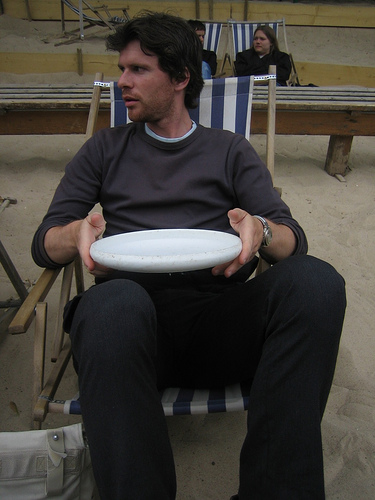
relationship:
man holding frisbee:
[33, 10, 346, 499] [91, 229, 242, 272]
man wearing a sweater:
[33, 10, 346, 499] [32, 123, 306, 269]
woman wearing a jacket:
[231, 26, 290, 84] [233, 48, 296, 85]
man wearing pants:
[33, 10, 346, 499] [71, 254, 348, 500]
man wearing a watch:
[33, 10, 346, 499] [255, 211, 271, 249]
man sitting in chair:
[33, 10, 346, 499] [9, 66, 279, 431]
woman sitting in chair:
[231, 26, 290, 84] [224, 18, 300, 88]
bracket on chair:
[92, 82, 111, 89] [9, 66, 279, 431]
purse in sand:
[0, 425, 84, 498] [1, 20, 373, 499]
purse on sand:
[0, 425, 84, 498] [1, 20, 373, 499]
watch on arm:
[255, 211, 271, 249] [216, 135, 308, 277]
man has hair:
[186, 20, 217, 78] [186, 18, 207, 32]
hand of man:
[78, 206, 108, 275] [33, 10, 346, 499]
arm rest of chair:
[8, 264, 57, 336] [9, 66, 279, 431]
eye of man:
[130, 64, 147, 77] [33, 10, 346, 499]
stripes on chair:
[108, 77, 252, 142] [9, 66, 279, 431]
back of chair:
[85, 64, 278, 193] [9, 66, 279, 431]